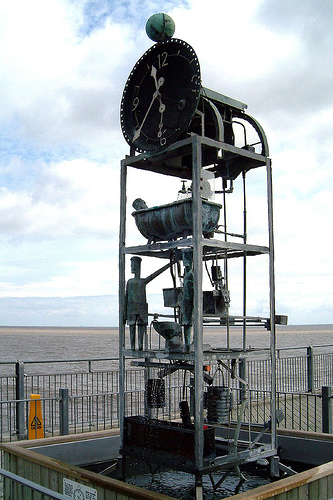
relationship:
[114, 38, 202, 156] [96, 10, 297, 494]
clock in tower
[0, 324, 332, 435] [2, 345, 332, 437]
water behind fence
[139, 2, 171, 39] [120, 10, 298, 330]
globe in tower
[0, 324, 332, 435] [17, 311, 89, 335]
water next to land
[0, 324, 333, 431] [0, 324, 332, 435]
ripple in water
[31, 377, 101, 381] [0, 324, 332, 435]
ripple in water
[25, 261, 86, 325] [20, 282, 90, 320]
hill in background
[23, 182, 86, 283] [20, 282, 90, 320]
sky in background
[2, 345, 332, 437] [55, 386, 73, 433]
fence next to object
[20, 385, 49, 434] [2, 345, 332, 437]
item next to fence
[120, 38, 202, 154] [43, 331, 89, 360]
clock near sea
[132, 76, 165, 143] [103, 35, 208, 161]
hand in clock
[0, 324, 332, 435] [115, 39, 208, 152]
water near clock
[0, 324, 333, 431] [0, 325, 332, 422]
ripple in sea water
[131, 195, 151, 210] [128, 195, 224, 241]
man in bath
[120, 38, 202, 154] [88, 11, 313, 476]
clock top tower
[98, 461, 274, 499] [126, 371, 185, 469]
water here splashing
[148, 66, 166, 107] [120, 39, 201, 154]
hand of clock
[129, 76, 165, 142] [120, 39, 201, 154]
hand of clock